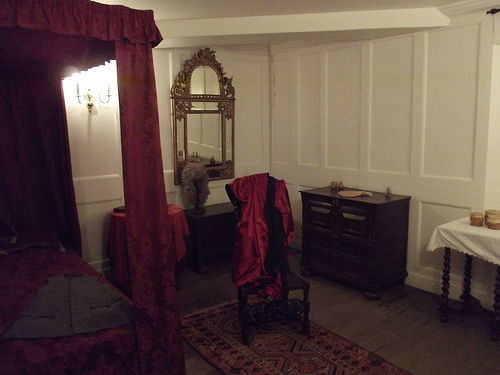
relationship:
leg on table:
[438, 247, 452, 324] [432, 215, 499, 342]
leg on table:
[460, 251, 475, 318] [432, 215, 499, 342]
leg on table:
[492, 265, 498, 335] [432, 215, 499, 342]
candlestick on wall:
[75, 71, 111, 111] [360, 59, 455, 134]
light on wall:
[95, 68, 120, 104] [59, 49, 269, 260]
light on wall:
[64, 68, 87, 106] [59, 49, 269, 260]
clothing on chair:
[223, 170, 298, 307] [223, 173, 315, 347]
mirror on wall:
[176, 94, 235, 166] [153, 44, 270, 203]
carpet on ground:
[169, 257, 404, 371] [105, 247, 483, 361]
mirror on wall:
[172, 49, 237, 185] [48, 0, 273, 283]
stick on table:
[438, 248, 451, 322] [427, 213, 499, 339]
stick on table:
[490, 266, 499, 342] [427, 213, 499, 339]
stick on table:
[460, 253, 472, 315] [427, 213, 499, 339]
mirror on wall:
[167, 43, 237, 189] [72, 40, 297, 256]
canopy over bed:
[9, 14, 170, 95] [38, 60, 170, 360]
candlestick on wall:
[76, 83, 111, 111] [69, 46, 272, 268]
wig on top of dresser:
[175, 160, 215, 213] [108, 187, 312, 275]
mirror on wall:
[172, 49, 237, 185] [2, 30, 271, 247]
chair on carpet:
[213, 156, 319, 341] [179, 294, 410, 374]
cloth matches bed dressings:
[111, 209, 188, 296] [0, 0, 191, 373]